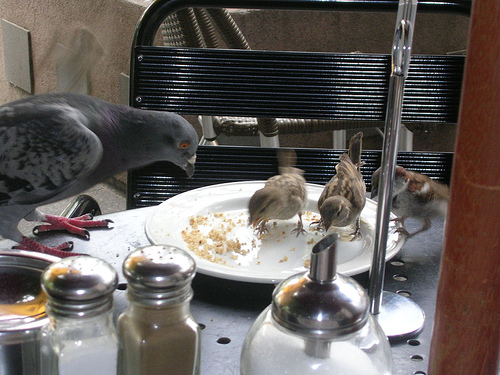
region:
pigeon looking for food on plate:
[0, 80, 201, 268]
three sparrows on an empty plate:
[237, 148, 457, 242]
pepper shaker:
[114, 239, 206, 373]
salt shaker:
[35, 249, 122, 374]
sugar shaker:
[231, 230, 397, 373]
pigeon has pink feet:
[11, 205, 116, 263]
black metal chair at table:
[121, 0, 471, 197]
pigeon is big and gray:
[0, 85, 200, 257]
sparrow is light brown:
[313, 128, 369, 243]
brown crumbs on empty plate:
[177, 200, 317, 275]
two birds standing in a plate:
[245, 150, 372, 239]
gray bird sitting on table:
[2, 78, 206, 250]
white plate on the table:
[142, 178, 395, 280]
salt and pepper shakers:
[49, 240, 196, 371]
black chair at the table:
[130, 5, 472, 198]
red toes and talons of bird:
[25, 213, 110, 263]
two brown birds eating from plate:
[245, 150, 370, 246]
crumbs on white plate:
[180, 198, 330, 271]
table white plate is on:
[4, 173, 454, 374]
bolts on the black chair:
[131, 53, 144, 206]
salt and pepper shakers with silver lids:
[28, 253, 205, 372]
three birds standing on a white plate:
[230, 146, 450, 251]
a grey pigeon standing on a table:
[0, 82, 211, 196]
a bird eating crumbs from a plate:
[196, 162, 311, 275]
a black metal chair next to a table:
[122, 9, 392, 184]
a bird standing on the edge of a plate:
[376, 148, 436, 257]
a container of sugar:
[248, 239, 394, 372]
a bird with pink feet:
[21, 198, 112, 279]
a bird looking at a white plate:
[148, 96, 243, 251]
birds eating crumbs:
[193, 148, 374, 271]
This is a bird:
[368, 154, 463, 260]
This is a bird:
[309, 122, 374, 237]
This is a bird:
[239, 156, 314, 248]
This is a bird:
[0, 82, 214, 264]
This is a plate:
[144, 168, 411, 280]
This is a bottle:
[119, 248, 202, 370]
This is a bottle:
[41, 251, 117, 371]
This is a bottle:
[249, 230, 384, 367]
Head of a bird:
[148, 100, 205, 185]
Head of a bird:
[243, 183, 279, 240]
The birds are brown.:
[239, 164, 467, 235]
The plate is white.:
[168, 169, 383, 281]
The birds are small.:
[233, 170, 458, 244]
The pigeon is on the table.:
[0, 101, 224, 241]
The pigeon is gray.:
[7, 76, 194, 254]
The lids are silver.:
[25, 241, 195, 293]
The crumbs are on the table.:
[175, 195, 253, 285]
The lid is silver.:
[255, 231, 392, 331]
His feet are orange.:
[18, 207, 110, 264]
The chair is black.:
[114, 2, 489, 208]